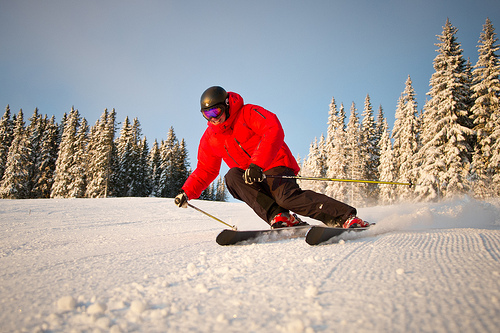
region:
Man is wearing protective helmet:
[197, 75, 237, 117]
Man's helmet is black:
[187, 82, 240, 122]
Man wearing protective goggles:
[194, 100, 235, 126]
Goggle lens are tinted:
[198, 106, 235, 124]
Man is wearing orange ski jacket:
[177, 90, 327, 181]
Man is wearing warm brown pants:
[213, 157, 382, 235]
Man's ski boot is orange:
[328, 209, 373, 231]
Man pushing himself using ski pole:
[168, 187, 243, 242]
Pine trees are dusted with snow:
[10, 93, 149, 207]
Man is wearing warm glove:
[241, 152, 266, 189]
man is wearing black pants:
[299, 188, 312, 215]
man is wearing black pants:
[297, 197, 308, 219]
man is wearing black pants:
[308, 179, 321, 222]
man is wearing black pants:
[289, 188, 306, 228]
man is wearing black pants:
[299, 200, 310, 215]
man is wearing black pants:
[284, 192, 296, 214]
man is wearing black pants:
[301, 200, 315, 234]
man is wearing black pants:
[313, 202, 324, 219]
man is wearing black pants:
[302, 199, 315, 217]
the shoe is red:
[349, 213, 358, 225]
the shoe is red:
[347, 218, 352, 222]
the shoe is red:
[342, 217, 353, 233]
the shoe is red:
[346, 219, 356, 226]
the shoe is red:
[350, 217, 359, 237]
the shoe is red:
[347, 215, 352, 237]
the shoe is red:
[344, 215, 356, 237]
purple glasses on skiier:
[198, 106, 228, 123]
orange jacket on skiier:
[177, 90, 302, 184]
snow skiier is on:
[122, 249, 270, 331]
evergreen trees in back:
[9, 66, 201, 220]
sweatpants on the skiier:
[215, 168, 339, 228]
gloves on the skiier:
[242, 158, 284, 196]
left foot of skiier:
[334, 205, 405, 251]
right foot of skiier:
[260, 202, 313, 231]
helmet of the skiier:
[190, 70, 230, 104]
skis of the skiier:
[212, 200, 409, 272]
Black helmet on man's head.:
[193, 85, 232, 105]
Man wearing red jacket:
[211, 122, 271, 144]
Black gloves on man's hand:
[240, 161, 266, 188]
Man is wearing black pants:
[229, 178, 306, 204]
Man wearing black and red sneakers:
[257, 210, 307, 228]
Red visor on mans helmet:
[191, 107, 235, 119]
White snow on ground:
[398, 222, 447, 330]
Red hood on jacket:
[226, 85, 247, 117]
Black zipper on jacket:
[229, 136, 254, 159]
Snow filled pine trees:
[46, 98, 126, 202]